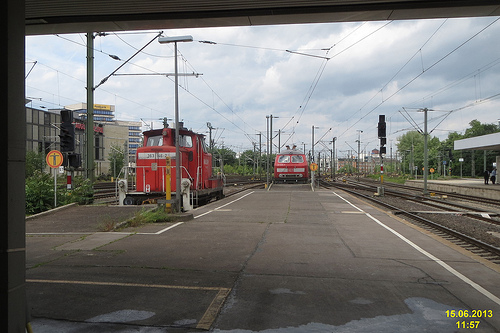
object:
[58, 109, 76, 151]
lights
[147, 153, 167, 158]
number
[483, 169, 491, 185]
people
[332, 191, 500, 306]
white lines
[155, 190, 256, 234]
white lines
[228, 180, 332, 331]
plateform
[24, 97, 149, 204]
buildings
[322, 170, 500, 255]
tracks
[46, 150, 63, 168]
sign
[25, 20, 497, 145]
lines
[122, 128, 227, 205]
train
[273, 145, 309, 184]
train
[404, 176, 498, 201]
platform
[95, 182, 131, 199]
train tracks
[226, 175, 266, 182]
train tracks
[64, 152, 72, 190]
pole